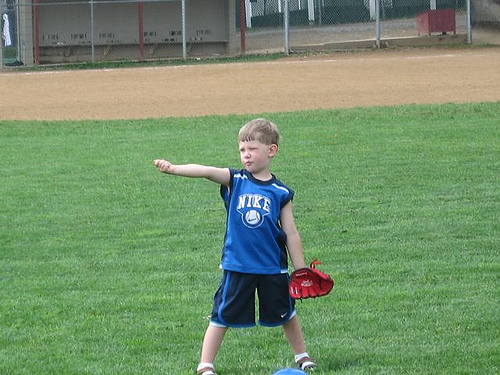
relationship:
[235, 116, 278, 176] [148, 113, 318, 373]
head of boy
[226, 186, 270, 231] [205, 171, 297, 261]
logo on shirt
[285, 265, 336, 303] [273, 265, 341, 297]
mitt on hand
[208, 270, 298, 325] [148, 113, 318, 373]
shorts on boy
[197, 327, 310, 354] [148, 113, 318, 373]
legs of boy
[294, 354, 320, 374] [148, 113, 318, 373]
sandal on boy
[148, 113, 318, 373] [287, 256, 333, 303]
boy wearing a mitt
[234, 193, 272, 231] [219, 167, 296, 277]
logo on shirt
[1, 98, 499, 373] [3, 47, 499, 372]
grass on baseball field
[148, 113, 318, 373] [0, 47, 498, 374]
boy standing in a baseball field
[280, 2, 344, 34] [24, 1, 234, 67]
fence near dugout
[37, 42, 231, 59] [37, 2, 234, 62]
bench in dugout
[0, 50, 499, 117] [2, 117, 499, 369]
dirt near infield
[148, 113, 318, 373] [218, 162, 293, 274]
boy wearing a shirt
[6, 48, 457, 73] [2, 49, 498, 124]
line in dirt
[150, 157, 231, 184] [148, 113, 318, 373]
arm of boy